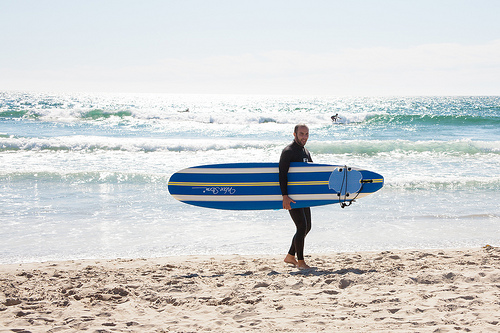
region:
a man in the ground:
[250, 97, 342, 310]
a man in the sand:
[261, 74, 333, 265]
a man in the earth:
[267, 109, 357, 300]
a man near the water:
[258, 85, 385, 285]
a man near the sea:
[259, 74, 329, 266]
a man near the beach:
[257, 88, 371, 324]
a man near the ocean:
[263, 98, 347, 270]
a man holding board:
[140, 128, 377, 211]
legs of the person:
[276, 203, 336, 238]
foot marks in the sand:
[102, 255, 278, 310]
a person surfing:
[326, 112, 345, 119]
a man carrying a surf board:
[171, 124, 393, 245]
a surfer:
[322, 108, 348, 123]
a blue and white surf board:
[169, 160, 371, 205]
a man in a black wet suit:
[276, 115, 328, 265]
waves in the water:
[28, 100, 478, 201]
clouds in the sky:
[11, 53, 480, 71]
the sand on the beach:
[4, 235, 484, 325]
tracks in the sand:
[24, 269, 495, 326]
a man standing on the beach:
[191, 120, 380, 243]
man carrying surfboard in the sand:
[165, 111, 394, 283]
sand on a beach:
[71, 269, 450, 326]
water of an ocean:
[13, 76, 143, 266]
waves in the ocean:
[367, 134, 486, 169]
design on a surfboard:
[327, 165, 366, 196]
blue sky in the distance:
[63, 14, 416, 77]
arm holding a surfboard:
[266, 144, 310, 216]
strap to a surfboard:
[338, 197, 359, 209]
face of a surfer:
[289, 117, 311, 149]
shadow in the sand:
[308, 250, 370, 280]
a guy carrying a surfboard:
[162, 121, 374, 262]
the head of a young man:
[290, 121, 314, 145]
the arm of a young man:
[274, 142, 298, 204]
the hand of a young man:
[277, 188, 292, 215]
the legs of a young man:
[280, 203, 322, 260]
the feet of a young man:
[287, 245, 319, 280]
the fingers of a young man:
[282, 199, 292, 216]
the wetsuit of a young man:
[268, 146, 330, 253]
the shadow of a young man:
[340, 251, 382, 289]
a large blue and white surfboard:
[175, 162, 377, 202]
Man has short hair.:
[289, 122, 321, 127]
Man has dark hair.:
[286, 117, 319, 144]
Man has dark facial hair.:
[290, 128, 308, 148]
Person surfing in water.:
[318, 109, 355, 131]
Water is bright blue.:
[58, 115, 113, 135]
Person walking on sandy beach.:
[268, 231, 330, 289]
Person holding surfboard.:
[258, 155, 318, 212]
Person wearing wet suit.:
[266, 136, 337, 265]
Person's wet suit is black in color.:
[276, 146, 325, 247]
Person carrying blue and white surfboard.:
[242, 153, 329, 215]